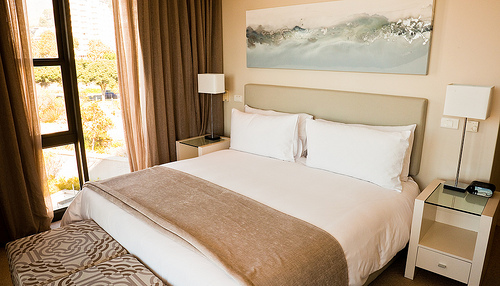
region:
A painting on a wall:
[243, 1, 434, 76]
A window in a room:
[14, 63, 69, 140]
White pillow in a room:
[228, 105, 299, 162]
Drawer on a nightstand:
[416, 245, 473, 282]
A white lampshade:
[445, 82, 492, 119]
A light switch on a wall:
[440, 117, 460, 129]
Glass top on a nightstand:
[423, 183, 488, 216]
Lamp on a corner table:
[196, 68, 229, 141]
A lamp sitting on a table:
[195, 71, 227, 140]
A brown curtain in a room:
[112, 0, 226, 172]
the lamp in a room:
[171, 42, 271, 157]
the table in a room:
[157, 100, 235, 177]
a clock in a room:
[466, 179, 498, 205]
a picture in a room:
[220, 2, 479, 90]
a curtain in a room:
[121, 11, 212, 161]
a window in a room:
[26, 10, 191, 190]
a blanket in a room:
[91, 148, 290, 266]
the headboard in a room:
[214, 81, 438, 164]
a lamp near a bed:
[156, 51, 267, 169]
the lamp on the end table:
[195, 66, 225, 144]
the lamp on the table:
[437, 71, 498, 199]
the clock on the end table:
[465, 179, 495, 201]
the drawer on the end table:
[415, 246, 471, 281]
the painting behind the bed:
[238, 3, 452, 88]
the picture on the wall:
[234, 0, 440, 82]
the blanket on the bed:
[93, 165, 333, 285]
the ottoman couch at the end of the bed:
[0, 217, 165, 284]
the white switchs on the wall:
[435, 115, 490, 136]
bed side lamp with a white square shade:
[431, 75, 496, 203]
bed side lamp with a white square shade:
[191, 68, 231, 143]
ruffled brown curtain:
[108, 1, 226, 175]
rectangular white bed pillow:
[222, 99, 302, 169]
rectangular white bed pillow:
[301, 111, 419, 202]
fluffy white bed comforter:
[50, 141, 427, 285]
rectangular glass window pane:
[0, 3, 65, 61]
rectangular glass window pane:
[18, 59, 78, 139]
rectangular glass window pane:
[20, 135, 94, 215]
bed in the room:
[76, 65, 416, 275]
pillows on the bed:
[216, 92, 398, 179]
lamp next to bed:
[438, 66, 496, 205]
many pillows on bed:
[219, 95, 403, 187]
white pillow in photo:
[298, 119, 400, 184]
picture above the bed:
[227, 2, 464, 80]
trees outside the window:
[81, 52, 123, 93]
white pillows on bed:
[224, 104, 307, 170]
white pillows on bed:
[308, 109, 418, 189]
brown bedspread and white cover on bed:
[104, 163, 337, 284]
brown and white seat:
[10, 220, 142, 284]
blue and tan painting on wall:
[239, 0, 437, 78]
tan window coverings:
[117, 9, 174, 150]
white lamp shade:
[443, 80, 493, 122]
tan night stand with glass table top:
[412, 175, 494, 283]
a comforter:
[240, 163, 295, 203]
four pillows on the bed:
[238, 107, 390, 188]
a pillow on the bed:
[312, 133, 384, 165]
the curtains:
[120, 18, 186, 123]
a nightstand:
[413, 188, 487, 285]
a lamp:
[195, 73, 223, 93]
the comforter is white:
[291, 165, 351, 215]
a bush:
[85, 110, 116, 147]